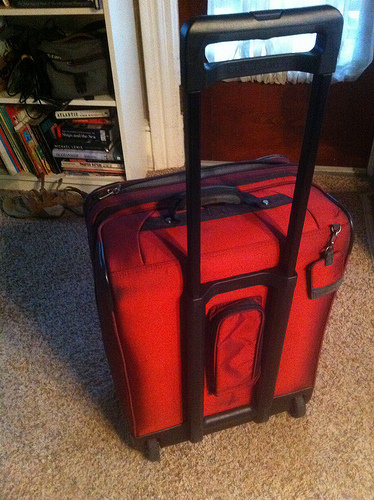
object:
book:
[55, 109, 110, 119]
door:
[178, 1, 374, 168]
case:
[82, 3, 353, 464]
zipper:
[330, 225, 341, 245]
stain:
[205, 300, 264, 398]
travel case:
[85, 7, 351, 462]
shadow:
[0, 221, 144, 449]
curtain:
[201, 1, 374, 82]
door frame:
[100, 0, 187, 180]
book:
[72, 119, 115, 125]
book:
[50, 119, 115, 141]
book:
[61, 159, 125, 174]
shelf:
[0, 93, 115, 107]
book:
[28, 114, 64, 174]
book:
[14, 112, 47, 178]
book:
[0, 105, 32, 173]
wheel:
[145, 438, 160, 462]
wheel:
[287, 397, 306, 417]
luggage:
[82, 5, 354, 463]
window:
[201, 0, 374, 80]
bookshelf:
[0, 129, 24, 176]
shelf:
[0, 175, 125, 194]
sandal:
[2, 187, 83, 218]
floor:
[1, 375, 107, 494]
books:
[55, 141, 114, 153]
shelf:
[0, 1, 104, 17]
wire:
[6, 57, 43, 120]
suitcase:
[81, 4, 355, 462]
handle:
[178, 2, 345, 279]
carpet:
[0, 168, 374, 500]